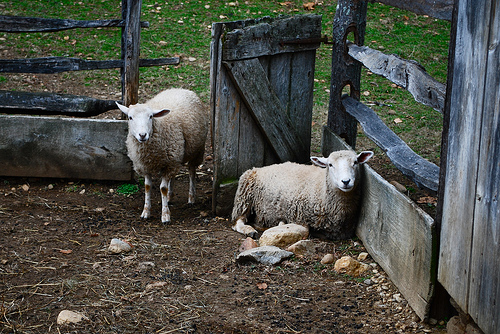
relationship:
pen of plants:
[8, 6, 447, 330] [30, 182, 374, 323]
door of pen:
[191, 7, 320, 201] [7, 3, 442, 292]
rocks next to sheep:
[46, 225, 139, 330] [103, 108, 373, 292]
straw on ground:
[75, 267, 155, 314] [43, 222, 208, 322]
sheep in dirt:
[129, 79, 199, 210] [40, 213, 170, 299]